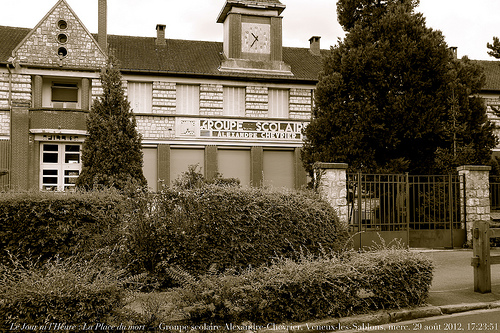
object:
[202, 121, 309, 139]
letters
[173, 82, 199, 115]
window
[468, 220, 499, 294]
post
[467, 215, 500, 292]
fence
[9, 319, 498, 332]
writing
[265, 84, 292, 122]
window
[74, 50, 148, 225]
tree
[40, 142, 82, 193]
entranceway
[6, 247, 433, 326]
hedge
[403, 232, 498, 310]
sidewalk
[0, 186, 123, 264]
bush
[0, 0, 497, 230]
building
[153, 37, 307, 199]
cuppola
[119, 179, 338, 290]
bush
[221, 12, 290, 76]
face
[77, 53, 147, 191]
pine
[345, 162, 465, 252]
gate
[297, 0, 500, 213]
tree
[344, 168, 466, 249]
fence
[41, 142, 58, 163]
window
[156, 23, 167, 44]
chimney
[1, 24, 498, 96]
roof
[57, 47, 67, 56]
circle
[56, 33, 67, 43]
circle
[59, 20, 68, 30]
circle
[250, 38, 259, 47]
hand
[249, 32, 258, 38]
hand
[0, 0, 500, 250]
school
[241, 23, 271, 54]
clock